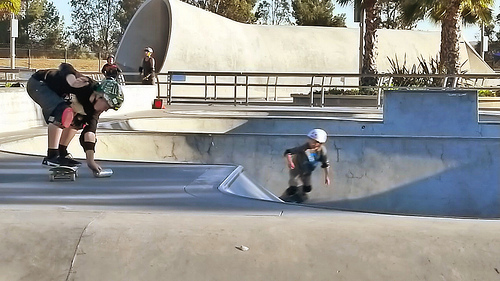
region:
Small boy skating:
[271, 123, 339, 207]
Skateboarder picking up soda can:
[24, 56, 126, 184]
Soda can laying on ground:
[91, 162, 121, 182]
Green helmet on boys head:
[91, 79, 129, 109]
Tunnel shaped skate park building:
[104, 2, 499, 94]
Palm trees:
[356, 0, 480, 91]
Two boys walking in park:
[96, 48, 168, 88]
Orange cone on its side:
[150, 92, 172, 112]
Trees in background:
[2, 0, 499, 56]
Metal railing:
[153, 67, 499, 111]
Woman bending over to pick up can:
[19, 59, 143, 187]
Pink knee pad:
[56, 103, 76, 130]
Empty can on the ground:
[91, 167, 120, 179]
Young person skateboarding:
[279, 109, 343, 200]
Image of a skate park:
[3, 82, 497, 270]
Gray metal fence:
[167, 66, 378, 106]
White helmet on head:
[304, 125, 329, 145]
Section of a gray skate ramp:
[218, 152, 298, 211]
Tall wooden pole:
[7, 10, 22, 77]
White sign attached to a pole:
[6, 12, 21, 43]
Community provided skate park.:
[6, 2, 493, 229]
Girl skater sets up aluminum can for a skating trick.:
[23, 61, 147, 189]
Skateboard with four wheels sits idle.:
[42, 155, 89, 185]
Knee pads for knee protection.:
[40, 95, 88, 141]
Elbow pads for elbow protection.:
[73, 124, 111, 158]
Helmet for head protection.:
[91, 72, 128, 114]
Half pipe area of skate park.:
[108, 127, 498, 209]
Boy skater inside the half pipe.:
[268, 120, 355, 230]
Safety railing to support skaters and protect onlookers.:
[173, 68, 498, 103]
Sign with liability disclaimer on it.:
[6, 11, 28, 67]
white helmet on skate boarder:
[292, 122, 330, 147]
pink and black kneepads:
[47, 105, 87, 132]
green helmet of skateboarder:
[86, 77, 129, 114]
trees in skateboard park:
[349, 6, 495, 93]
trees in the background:
[24, 4, 112, 85]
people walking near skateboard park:
[80, 48, 165, 88]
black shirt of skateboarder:
[32, 71, 109, 150]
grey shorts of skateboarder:
[30, 69, 67, 119]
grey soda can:
[80, 160, 113, 185]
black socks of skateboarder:
[38, 146, 88, 178]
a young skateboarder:
[23, 47, 126, 189]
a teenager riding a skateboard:
[277, 115, 344, 208]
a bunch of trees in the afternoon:
[0, 0, 115, 45]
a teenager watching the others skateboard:
[131, 41, 158, 85]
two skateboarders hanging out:
[101, 32, 158, 84]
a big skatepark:
[38, 11, 443, 213]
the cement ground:
[35, 204, 447, 271]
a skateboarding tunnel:
[107, 0, 305, 80]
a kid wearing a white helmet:
[279, 122, 338, 217]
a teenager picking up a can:
[21, 58, 124, 183]